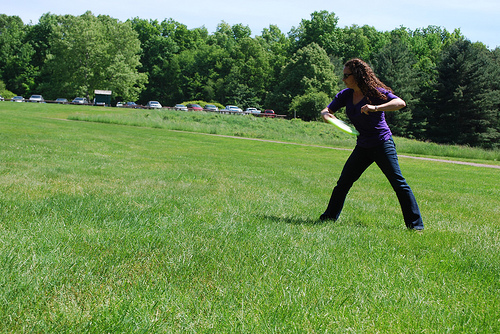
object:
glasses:
[343, 72, 354, 78]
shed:
[93, 90, 112, 107]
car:
[28, 84, 44, 101]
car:
[121, 93, 139, 103]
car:
[179, 103, 184, 110]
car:
[115, 100, 125, 106]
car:
[14, 94, 24, 101]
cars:
[1, 94, 282, 117]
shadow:
[256, 210, 331, 229]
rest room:
[93, 89, 112, 107]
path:
[205, 130, 499, 170]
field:
[0, 95, 498, 331]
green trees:
[61, 12, 291, 101]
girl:
[315, 58, 425, 232]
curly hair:
[343, 58, 395, 105]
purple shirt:
[325, 86, 398, 142]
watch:
[374, 104, 379, 112]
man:
[318, 58, 423, 232]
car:
[188, 101, 203, 111]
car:
[225, 103, 244, 113]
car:
[70, 94, 92, 105]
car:
[142, 98, 164, 108]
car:
[174, 102, 188, 111]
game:
[3, 55, 497, 237]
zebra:
[324, 113, 361, 137]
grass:
[0, 122, 322, 332]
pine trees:
[381, 38, 496, 140]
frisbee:
[318, 108, 353, 137]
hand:
[361, 104, 376, 115]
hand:
[321, 109, 337, 123]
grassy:
[28, 129, 243, 263]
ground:
[206, 158, 416, 305]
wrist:
[373, 103, 385, 112]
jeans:
[319, 133, 423, 231]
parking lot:
[0, 93, 279, 120]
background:
[2, 29, 498, 119]